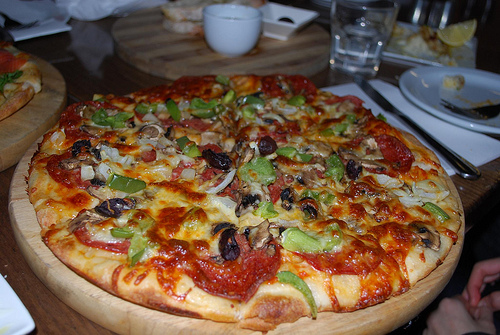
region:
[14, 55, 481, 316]
a delicious looking pizza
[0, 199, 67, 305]
a wooden platform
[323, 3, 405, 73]
a glass on the table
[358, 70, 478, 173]
a knife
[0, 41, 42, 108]
another pizza in the corner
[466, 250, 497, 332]
a hand below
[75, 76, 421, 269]
lots of toppings on the pizza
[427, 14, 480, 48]
a lemon wedge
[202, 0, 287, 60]
a white cup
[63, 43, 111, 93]
a brown table in the background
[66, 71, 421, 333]
pizza on wood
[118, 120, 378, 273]
pizza with many different toppings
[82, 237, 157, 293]
brown crust of pizza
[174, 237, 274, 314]
red topping on the pizza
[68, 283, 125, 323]
wood under the pizza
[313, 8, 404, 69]
clear glass next to pizza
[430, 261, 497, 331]
person's hands near pizza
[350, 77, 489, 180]
knife next to pizza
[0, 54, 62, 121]
side of a pizza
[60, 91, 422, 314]
round pizza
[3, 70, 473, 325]
A PIZZA ON A SERVING BOARD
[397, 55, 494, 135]
A PLATE WITH A FORK ON IT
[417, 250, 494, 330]
TWO HANDS IN THE BOTTOM RIGHT OF THE PHOTO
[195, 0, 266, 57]
A WHITE BOWL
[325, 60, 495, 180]
A BUTTER KNIFE ON A NAPKIN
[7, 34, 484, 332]
A PICTURE OF A WHOLE PIZZA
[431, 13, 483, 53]
A SLICE OF LEMON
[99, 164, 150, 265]
GREEN PEPPERS ON A PIZZA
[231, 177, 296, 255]
MUSHROOMS ON A PIZZA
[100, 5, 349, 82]
A WOODEN SERVING BOARD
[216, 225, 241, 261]
a black olive on the pizza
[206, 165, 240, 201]
a white onion slice on the pizza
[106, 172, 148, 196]
a green pepper on the pizza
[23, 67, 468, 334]
a pizza on the wood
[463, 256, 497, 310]
the finger of the person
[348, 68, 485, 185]
a metal knife on the napkin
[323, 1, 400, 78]
a clear drinking glass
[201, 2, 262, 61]
a white bowl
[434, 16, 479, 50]
a yellow lemon wedge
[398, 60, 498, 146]
a white plate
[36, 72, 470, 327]
a pizza on a wooden plate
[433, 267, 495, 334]
two hands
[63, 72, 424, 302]
a pizza with pepperoni, black olives and green peppers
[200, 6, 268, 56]
a white cup on a wooden plate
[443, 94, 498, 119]
the tip of a fork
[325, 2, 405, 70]
an empty glass of water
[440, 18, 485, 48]
a lemon slice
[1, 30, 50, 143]
the edge of a pizza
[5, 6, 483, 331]
a table with food and plates